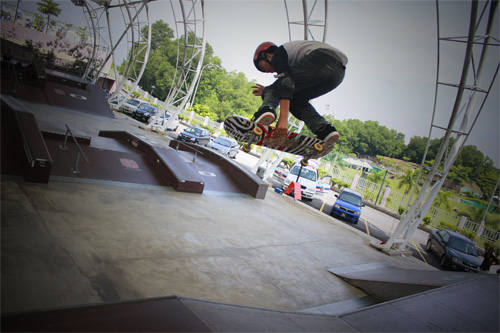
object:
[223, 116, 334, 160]
skate board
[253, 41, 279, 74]
helmet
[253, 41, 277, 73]
head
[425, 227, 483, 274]
car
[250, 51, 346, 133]
black pants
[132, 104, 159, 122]
car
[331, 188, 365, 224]
car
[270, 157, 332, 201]
car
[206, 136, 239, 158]
car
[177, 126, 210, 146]
car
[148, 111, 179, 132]
car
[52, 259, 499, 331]
ramp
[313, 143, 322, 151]
tires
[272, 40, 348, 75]
t-shirt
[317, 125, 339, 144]
shoe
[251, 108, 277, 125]
shoe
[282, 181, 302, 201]
sign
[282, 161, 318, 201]
car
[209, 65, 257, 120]
tree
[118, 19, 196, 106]
tree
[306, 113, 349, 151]
tree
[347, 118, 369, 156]
tree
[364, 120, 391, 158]
tree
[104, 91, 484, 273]
lot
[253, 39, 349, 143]
boy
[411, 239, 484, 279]
spot